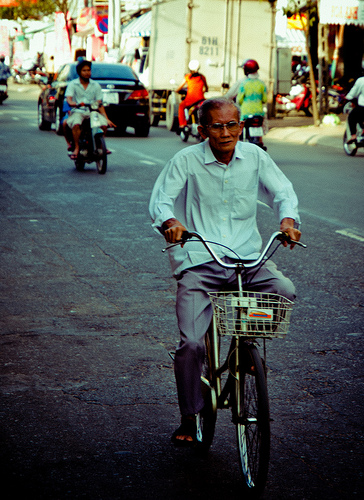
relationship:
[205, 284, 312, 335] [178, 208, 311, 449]
basket on bike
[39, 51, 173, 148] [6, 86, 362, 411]
car on road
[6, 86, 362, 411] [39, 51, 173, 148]
road under car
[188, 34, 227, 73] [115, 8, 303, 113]
numbers on building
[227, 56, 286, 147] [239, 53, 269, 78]
person wearing helmet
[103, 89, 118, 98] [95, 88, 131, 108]
white license plate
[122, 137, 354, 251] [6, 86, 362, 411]
line on road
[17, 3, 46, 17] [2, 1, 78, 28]
leaves on trees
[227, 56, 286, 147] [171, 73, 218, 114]
person in orange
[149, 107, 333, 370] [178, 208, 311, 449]
man on bike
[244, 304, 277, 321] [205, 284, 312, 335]
sign on basket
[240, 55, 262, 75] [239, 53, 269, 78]
red motorcycle helmet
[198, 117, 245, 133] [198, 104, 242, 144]
glasses on face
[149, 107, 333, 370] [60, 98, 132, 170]
man on scooter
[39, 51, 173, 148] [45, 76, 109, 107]
car in distance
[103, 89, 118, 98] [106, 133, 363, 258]
white dotted line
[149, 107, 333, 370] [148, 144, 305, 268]
man wearing shirt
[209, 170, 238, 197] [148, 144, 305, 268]
buttons on shirt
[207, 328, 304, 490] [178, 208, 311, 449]
wheel on bike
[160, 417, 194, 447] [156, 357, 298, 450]
feet on pedals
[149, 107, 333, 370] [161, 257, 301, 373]
man wearing pants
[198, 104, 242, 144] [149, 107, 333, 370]
face of man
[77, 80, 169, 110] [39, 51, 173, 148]
back of car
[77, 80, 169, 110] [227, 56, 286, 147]
back of woman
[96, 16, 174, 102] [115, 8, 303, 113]
side of truck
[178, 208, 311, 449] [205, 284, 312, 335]
bike has basket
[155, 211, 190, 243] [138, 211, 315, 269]
hands on handles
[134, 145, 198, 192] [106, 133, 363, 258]
painted white line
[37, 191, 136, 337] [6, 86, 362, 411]
black paved road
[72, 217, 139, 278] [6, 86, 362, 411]
crack on road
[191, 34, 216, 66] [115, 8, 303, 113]
writing on truck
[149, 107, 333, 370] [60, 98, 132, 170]
man on moped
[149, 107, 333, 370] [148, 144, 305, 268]
man in shirt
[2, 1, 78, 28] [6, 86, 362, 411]
trees on road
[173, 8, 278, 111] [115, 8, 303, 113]
rear of truck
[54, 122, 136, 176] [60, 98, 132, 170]
wheels on scooter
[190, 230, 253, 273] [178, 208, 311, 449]
cables on bike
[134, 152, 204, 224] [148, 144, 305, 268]
long sleeve shirt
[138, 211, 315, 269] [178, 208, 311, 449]
bars on bike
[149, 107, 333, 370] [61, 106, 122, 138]
man wearing shorts